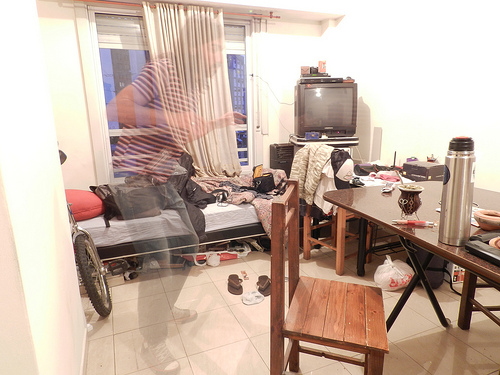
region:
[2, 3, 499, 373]
transparent image of man in cluttered room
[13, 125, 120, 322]
bicycle partially visible near wall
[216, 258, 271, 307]
brown flip-flops on the ground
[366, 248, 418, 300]
tied plastic bag on the ground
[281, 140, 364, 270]
clothing thrown over the back of a chair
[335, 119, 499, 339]
dark table near wall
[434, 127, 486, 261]
silver and black thermos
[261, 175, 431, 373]
wooden chair near table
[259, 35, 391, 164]
television near wall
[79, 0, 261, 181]
curtain in front of large window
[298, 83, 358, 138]
this is a television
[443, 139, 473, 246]
this is a thermos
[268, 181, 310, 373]
this is a chair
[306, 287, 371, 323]
the chair is wooden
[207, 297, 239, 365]
the floor is made of tiles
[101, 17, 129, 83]
this is a window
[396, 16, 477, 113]
the wall is white in color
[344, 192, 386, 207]
this is a table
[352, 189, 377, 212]
the table is wooden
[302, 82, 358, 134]
the television is off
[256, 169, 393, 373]
a wooden chair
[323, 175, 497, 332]
a table holding stuff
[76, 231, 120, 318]
a bicycle tire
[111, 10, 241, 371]
a man dancing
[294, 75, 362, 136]
a television screen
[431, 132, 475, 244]
a thermos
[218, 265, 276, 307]
a pair of sandals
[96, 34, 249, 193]
a window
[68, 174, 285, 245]
a bed that has cloths on it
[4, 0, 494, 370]
an unorganized room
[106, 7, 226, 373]
the person is see thru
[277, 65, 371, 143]
the tv is black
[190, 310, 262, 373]
the ground is white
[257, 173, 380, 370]
the chair is brown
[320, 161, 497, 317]
the table is brown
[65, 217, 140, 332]
the tire is small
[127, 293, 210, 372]
the person has shoes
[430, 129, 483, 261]
the thermos is silver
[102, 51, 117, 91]
the sky is blue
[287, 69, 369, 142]
the tv is blue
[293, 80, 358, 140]
a gray television in the corner of the room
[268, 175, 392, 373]
a brown wooden chair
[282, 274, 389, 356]
the seat of a wooden chair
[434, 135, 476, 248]
a black and silver thermos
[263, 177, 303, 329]
the back of a wooden chair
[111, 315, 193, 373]
a white tile on the floor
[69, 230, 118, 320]
a black wheel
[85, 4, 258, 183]
the window in a room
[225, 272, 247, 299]
a brown flip flop on the floor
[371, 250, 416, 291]
a white plastic bag on the floor